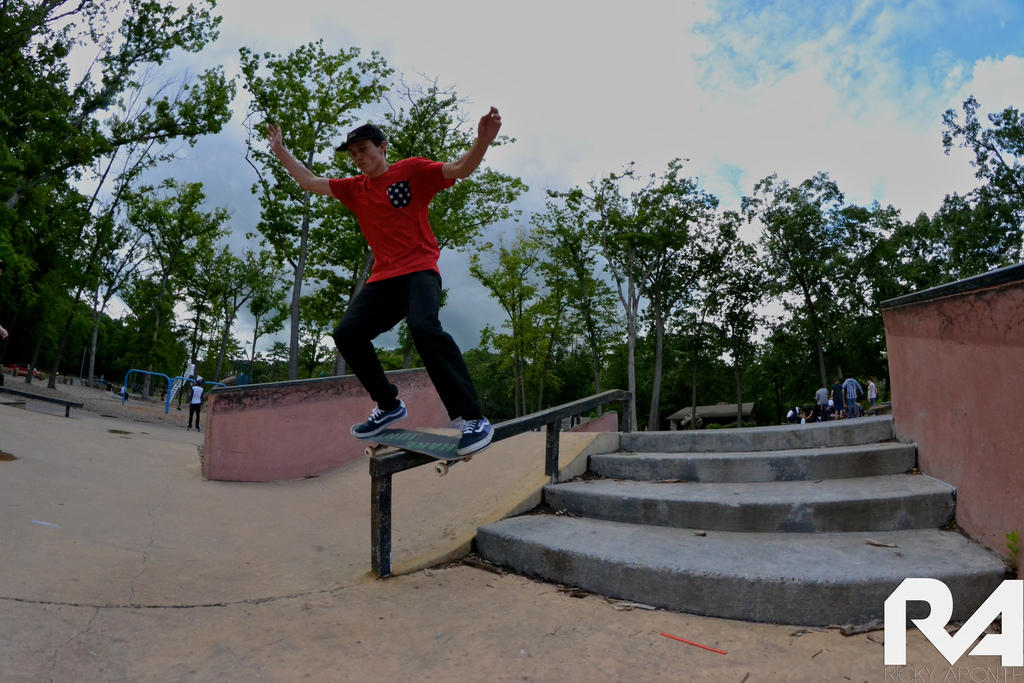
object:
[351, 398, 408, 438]
shoe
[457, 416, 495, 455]
shoe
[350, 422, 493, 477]
skateboard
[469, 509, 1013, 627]
step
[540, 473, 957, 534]
step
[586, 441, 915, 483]
step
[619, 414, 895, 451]
step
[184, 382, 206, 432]
person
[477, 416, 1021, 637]
stairway